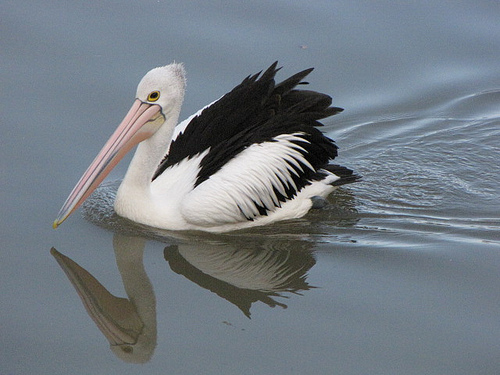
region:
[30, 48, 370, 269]
dock white and black in water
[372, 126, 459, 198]
water ripples in water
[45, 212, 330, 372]
reflection of bird in water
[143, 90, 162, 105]
eye of bird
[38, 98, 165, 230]
long beak of animal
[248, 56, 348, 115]
black feathers of bird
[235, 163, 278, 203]
white feathers of bird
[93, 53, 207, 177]
head of bird white and black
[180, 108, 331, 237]
white and black wing of bird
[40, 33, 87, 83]
calm dark water in pond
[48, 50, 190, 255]
head of a bird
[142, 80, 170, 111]
eye of a bird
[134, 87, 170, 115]
an eye of a bird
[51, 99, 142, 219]
peck of a bird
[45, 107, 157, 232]
mouth of a bird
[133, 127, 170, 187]
neck of a bird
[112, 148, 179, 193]
a neck of a bird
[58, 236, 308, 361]
reflections of a bird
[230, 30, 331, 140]
feather of a bird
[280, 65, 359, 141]
tail of a bird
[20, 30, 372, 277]
a pelican in the water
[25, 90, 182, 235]
the pelican's beak is pink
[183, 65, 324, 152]
the pelican has black feathers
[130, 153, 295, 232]
this part of the pelican's feathers is white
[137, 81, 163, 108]
the pelican's eyes are yellow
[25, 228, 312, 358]
the reflection of the pelican is in the water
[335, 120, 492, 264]
the pelican is making waves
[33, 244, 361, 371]
the water is clear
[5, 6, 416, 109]
the water behind the pelican is calm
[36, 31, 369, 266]
a pelican is a bird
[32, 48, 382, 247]
a beautiful pelican takes a swim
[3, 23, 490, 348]
the water is dead calm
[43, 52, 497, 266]
the pelican leaves a small wave in its wake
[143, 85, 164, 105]
pelican has gentle yellow eyes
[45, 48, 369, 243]
pelican's feathers are black and white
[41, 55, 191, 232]
pelican's long beak is designed for catching fish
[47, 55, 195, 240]
pelican's lower beak stretches into a pouch for holding fish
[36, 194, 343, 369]
pelican's reflection is clearly visible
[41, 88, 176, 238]
pelican's beak is edged in blue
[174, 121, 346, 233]
pelican's white feathers are tipped in black